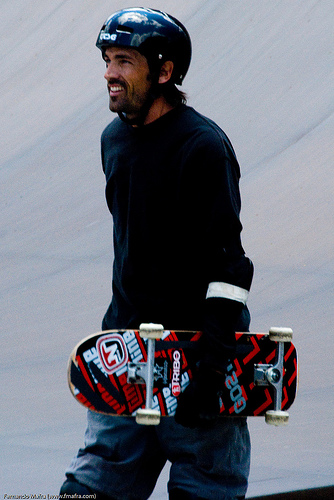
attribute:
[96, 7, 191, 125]
helmet — black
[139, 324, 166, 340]
wheel — white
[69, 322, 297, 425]
skateboard — black, red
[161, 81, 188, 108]
hair — long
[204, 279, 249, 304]
stripe — white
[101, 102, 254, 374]
shirt — black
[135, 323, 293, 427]
wheels — white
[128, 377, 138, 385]
screw — black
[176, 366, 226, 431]
gloves — black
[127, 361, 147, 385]
bracket — silver